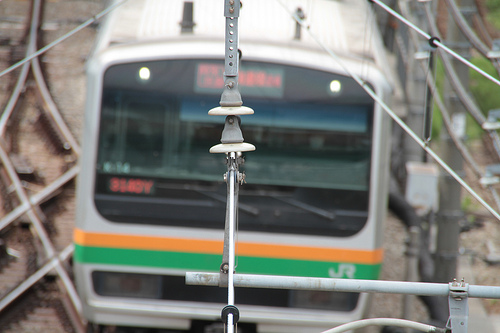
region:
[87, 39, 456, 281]
a train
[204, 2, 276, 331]
silver pole apparatus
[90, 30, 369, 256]
front windshield of a bus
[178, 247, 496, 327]
metal railing connected to wires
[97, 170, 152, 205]
reader screen on a train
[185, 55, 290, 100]
train name and location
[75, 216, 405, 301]
orange and green stripes on a train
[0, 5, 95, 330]
railroad tracks crossing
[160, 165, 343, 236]
windshield wipers on the train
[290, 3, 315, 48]
exhaust on the top of the train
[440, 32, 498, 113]
green grass behind railroad station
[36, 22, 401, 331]
front of a train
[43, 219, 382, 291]
orange and green lines on the front of train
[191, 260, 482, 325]
metal pole in picture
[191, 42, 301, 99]
electronic sign on train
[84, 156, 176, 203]
electronic sign on train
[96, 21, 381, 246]
front window on the train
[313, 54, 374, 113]
front right light on train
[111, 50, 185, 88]
front left light on train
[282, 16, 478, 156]
metal cables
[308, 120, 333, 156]
front window of a train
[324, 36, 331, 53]
top of a train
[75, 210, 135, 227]
edge of a train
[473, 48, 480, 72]
part of the ground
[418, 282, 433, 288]
part of a steel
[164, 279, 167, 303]
bottom of a train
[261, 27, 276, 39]
roof of a train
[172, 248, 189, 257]
yellow stripe on a train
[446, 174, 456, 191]
edge of a tain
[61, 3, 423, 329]
the train is silver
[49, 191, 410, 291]
the train has a green stripe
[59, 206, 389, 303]
the train has an orange stripe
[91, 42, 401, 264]
the train has a windshield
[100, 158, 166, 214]
the train has red numbers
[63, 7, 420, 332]
the train is blurry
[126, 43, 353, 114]
the train has two white lights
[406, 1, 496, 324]
a telephone pole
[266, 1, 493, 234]
silver wires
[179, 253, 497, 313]
the pole is gray